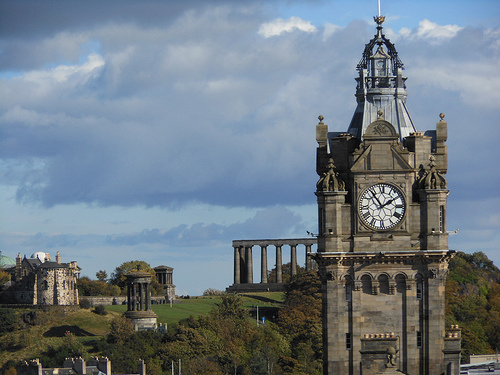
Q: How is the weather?
A: It is cloudy.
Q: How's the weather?
A: It is cloudy.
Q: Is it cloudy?
A: Yes, it is cloudy.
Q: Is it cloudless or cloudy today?
A: It is cloudy.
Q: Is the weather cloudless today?
A: No, it is cloudy.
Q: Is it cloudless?
A: No, it is cloudy.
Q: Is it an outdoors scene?
A: Yes, it is outdoors.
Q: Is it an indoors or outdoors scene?
A: It is outdoors.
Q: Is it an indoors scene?
A: No, it is outdoors.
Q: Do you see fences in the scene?
A: No, there are no fences.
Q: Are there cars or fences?
A: No, there are no fences or cars.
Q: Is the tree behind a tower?
A: Yes, the tree is behind a tower.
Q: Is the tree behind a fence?
A: No, the tree is behind a tower.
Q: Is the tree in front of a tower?
A: No, the tree is behind a tower.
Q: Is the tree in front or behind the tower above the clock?
A: The tree is behind the tower.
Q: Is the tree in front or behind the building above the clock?
A: The tree is behind the tower.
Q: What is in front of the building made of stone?
A: The tree is in front of the building.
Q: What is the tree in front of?
A: The tree is in front of the building.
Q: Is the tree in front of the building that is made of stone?
A: Yes, the tree is in front of the building.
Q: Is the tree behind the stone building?
A: No, the tree is in front of the building.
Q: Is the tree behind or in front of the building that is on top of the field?
A: The tree is in front of the building.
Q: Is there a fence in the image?
A: No, there are no fences.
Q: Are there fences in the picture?
A: No, there are no fences.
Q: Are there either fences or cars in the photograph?
A: No, there are no fences or cars.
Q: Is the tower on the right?
A: Yes, the tower is on the right of the image.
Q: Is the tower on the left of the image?
A: No, the tower is on the right of the image.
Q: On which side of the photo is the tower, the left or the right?
A: The tower is on the right of the image.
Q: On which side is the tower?
A: The tower is on the right of the image.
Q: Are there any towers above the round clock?
A: Yes, there is a tower above the clock.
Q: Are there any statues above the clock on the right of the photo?
A: No, there is a tower above the clock.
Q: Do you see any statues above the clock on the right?
A: No, there is a tower above the clock.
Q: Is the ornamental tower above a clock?
A: Yes, the tower is above a clock.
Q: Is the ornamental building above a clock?
A: Yes, the tower is above a clock.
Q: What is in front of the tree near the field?
A: The tower is in front of the tree.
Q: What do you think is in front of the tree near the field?
A: The tower is in front of the tree.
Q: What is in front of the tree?
A: The tower is in front of the tree.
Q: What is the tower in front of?
A: The tower is in front of the tree.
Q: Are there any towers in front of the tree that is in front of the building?
A: Yes, there is a tower in front of the tree.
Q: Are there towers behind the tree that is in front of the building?
A: No, the tower is in front of the tree.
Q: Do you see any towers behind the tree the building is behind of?
A: No, the tower is in front of the tree.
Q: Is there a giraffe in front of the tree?
A: No, there is a tower in front of the tree.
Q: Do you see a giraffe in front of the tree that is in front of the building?
A: No, there is a tower in front of the tree.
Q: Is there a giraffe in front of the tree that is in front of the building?
A: No, there is a tower in front of the tree.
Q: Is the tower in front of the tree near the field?
A: Yes, the tower is in front of the tree.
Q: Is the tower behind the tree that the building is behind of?
A: No, the tower is in front of the tree.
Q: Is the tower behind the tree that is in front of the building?
A: No, the tower is in front of the tree.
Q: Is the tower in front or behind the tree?
A: The tower is in front of the tree.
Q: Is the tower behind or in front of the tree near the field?
A: The tower is in front of the tree.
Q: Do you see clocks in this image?
A: Yes, there is a clock.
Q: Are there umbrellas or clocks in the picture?
A: Yes, there is a clock.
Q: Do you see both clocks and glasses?
A: No, there is a clock but no glasses.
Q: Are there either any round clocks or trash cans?
A: Yes, there is a round clock.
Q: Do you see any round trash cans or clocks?
A: Yes, there is a round clock.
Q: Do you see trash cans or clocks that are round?
A: Yes, the clock is round.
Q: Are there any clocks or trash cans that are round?
A: Yes, the clock is round.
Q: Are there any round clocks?
A: Yes, there is a round clock.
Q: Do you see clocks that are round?
A: Yes, there is a clock that is round.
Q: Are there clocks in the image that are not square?
A: Yes, there is a round clock.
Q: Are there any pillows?
A: No, there are no pillows.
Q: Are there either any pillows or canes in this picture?
A: No, there are no pillows or canes.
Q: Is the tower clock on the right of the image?
A: Yes, the clock is on the right of the image.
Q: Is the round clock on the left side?
A: No, the clock is on the right of the image.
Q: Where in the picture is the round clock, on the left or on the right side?
A: The clock is on the right of the image.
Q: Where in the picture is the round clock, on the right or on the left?
A: The clock is on the right of the image.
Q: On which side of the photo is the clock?
A: The clock is on the right of the image.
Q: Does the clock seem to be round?
A: Yes, the clock is round.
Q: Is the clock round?
A: Yes, the clock is round.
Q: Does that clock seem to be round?
A: Yes, the clock is round.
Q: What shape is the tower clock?
A: The clock is round.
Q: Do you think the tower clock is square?
A: No, the clock is round.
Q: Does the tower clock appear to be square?
A: No, the clock is round.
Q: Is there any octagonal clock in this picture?
A: No, there is a clock but it is round.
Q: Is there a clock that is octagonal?
A: No, there is a clock but it is round.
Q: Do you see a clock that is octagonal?
A: No, there is a clock but it is round.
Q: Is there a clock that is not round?
A: No, there is a clock but it is round.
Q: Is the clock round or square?
A: The clock is round.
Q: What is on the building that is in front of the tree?
A: The clock is on the tower.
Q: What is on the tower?
A: The clock is on the tower.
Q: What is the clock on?
A: The clock is on the tower.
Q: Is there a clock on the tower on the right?
A: Yes, there is a clock on the tower.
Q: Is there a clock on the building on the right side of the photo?
A: Yes, there is a clock on the tower.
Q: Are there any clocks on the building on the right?
A: Yes, there is a clock on the tower.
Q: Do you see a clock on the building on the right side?
A: Yes, there is a clock on the tower.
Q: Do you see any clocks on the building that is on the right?
A: Yes, there is a clock on the tower.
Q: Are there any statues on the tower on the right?
A: No, there is a clock on the tower.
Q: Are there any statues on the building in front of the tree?
A: No, there is a clock on the tower.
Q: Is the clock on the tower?
A: Yes, the clock is on the tower.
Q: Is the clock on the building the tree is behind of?
A: Yes, the clock is on the tower.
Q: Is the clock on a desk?
A: No, the clock is on the tower.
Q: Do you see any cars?
A: No, there are no cars.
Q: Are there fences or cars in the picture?
A: No, there are no cars or fences.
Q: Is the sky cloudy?
A: Yes, the sky is cloudy.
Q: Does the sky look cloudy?
A: Yes, the sky is cloudy.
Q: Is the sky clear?
A: No, the sky is cloudy.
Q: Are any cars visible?
A: No, there are no cars.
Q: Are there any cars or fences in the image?
A: No, there are no cars or fences.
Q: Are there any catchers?
A: No, there are no catchers.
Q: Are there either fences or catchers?
A: No, there are no catchers or fences.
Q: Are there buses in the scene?
A: No, there are no buses.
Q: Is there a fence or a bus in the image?
A: No, there are no buses or fences.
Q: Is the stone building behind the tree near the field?
A: Yes, the building is behind the tree.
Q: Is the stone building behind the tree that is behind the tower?
A: Yes, the building is behind the tree.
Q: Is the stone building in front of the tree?
A: No, the building is behind the tree.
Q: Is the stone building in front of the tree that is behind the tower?
A: No, the building is behind the tree.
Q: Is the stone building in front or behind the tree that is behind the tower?
A: The building is behind the tree.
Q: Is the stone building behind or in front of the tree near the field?
A: The building is behind the tree.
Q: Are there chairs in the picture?
A: No, there are no chairs.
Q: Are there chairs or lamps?
A: No, there are no chairs or lamps.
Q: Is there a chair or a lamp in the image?
A: No, there are no chairs or lamps.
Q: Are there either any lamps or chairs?
A: No, there are no chairs or lamps.